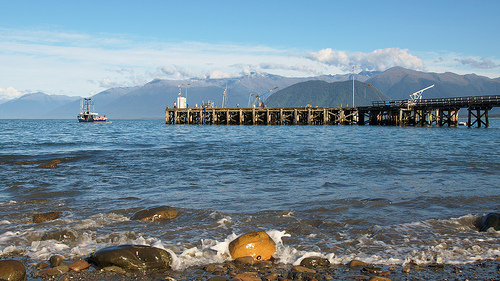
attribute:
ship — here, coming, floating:
[78, 94, 109, 125]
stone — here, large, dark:
[92, 243, 173, 267]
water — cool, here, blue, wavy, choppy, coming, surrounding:
[0, 115, 499, 271]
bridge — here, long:
[162, 96, 499, 125]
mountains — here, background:
[7, 66, 500, 122]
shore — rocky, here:
[1, 223, 500, 280]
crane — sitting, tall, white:
[407, 80, 437, 102]